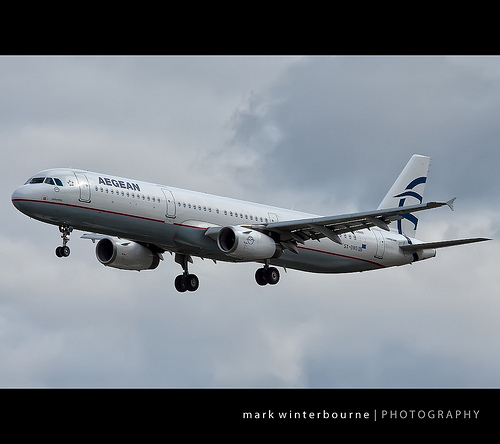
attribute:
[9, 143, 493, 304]
plane — grey, red, white, flying, large, gray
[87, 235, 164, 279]
engine — large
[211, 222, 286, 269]
engine — large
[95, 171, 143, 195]
letters — dark blue, blue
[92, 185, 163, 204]
windows — small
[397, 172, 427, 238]
symbol — blue, large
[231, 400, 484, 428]
words — white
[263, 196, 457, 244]
wings — grey, large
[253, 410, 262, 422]
letter — white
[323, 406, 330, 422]
letter — white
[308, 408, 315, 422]
letter — white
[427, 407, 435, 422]
letter — white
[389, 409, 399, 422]
letter — white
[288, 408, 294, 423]
letter — white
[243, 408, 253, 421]
letter — white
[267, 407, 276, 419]
letter — white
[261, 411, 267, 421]
letter — white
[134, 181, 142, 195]
letter — blue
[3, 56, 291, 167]
sky — cloudy, gray, white, dark